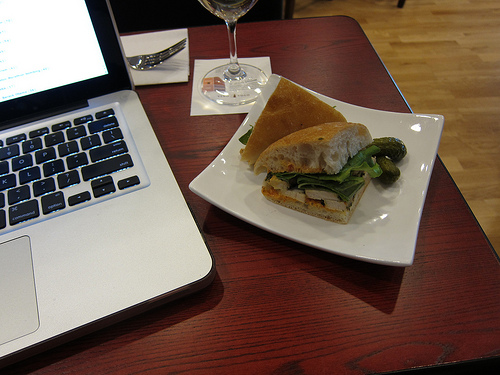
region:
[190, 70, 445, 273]
a sandwich on a white plate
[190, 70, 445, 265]
a square white plate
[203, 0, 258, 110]
a glass with a stem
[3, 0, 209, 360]
a white lap top computer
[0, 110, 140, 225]
black buttons on a computer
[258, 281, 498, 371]
a wood grain desk top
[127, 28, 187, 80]
a fork on a napkin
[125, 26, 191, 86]
a white napkin under a plate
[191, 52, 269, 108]
a white paper under a glass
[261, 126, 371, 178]
a bun on a sandwich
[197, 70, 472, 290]
A sandwich on a plate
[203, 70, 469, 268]
Lunch on a plate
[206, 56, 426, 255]
Two halves of a sandwich on a plate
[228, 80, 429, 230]
A sandwich cut in half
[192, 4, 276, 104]
A wine glass on a napkin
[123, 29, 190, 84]
A fork on a napkin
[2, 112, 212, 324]
A keyboard on a laptop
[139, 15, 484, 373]
A wooden table with food on it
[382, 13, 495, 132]
Wood on the floor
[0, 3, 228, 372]
A laptop on a wooden table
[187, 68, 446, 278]
square white ceramic plate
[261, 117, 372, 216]
mushroom and lettuce on ciabotta bread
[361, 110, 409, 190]
baby gherkin pickles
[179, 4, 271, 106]
a single piece of stemware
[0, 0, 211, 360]
a silver colored laptop computer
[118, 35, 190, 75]
stainless steel fork tines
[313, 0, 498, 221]
light wood pattern flooring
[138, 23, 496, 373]
dark cherry wood look Formica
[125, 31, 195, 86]
white paper napkin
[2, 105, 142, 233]
blue light shine through keys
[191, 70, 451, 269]
plate with sandwich on it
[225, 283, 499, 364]
wooden table with several items on it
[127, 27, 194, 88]
fork on white napkin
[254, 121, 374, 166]
top slice of bread on sandwich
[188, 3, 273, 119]
glass resting on napkin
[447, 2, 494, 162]
wooden floor in room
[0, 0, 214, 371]
laptop computer on desk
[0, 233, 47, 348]
mouse pad area of computer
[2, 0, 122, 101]
screen area of computer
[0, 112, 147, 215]
keys on the computer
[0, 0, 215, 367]
Open white and black laptop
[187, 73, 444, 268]
Fancy square white plate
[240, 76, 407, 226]
Two halves of a sandwich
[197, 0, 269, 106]
Water in a wine glass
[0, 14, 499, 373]
Small mahogany dining table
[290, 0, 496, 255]
Light brown wood floor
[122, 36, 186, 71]
Eating end of a silver fork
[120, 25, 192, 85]
Folded white paper napkin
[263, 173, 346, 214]
Slices of chicken on a sandwich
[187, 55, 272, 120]
Square white piece of paper